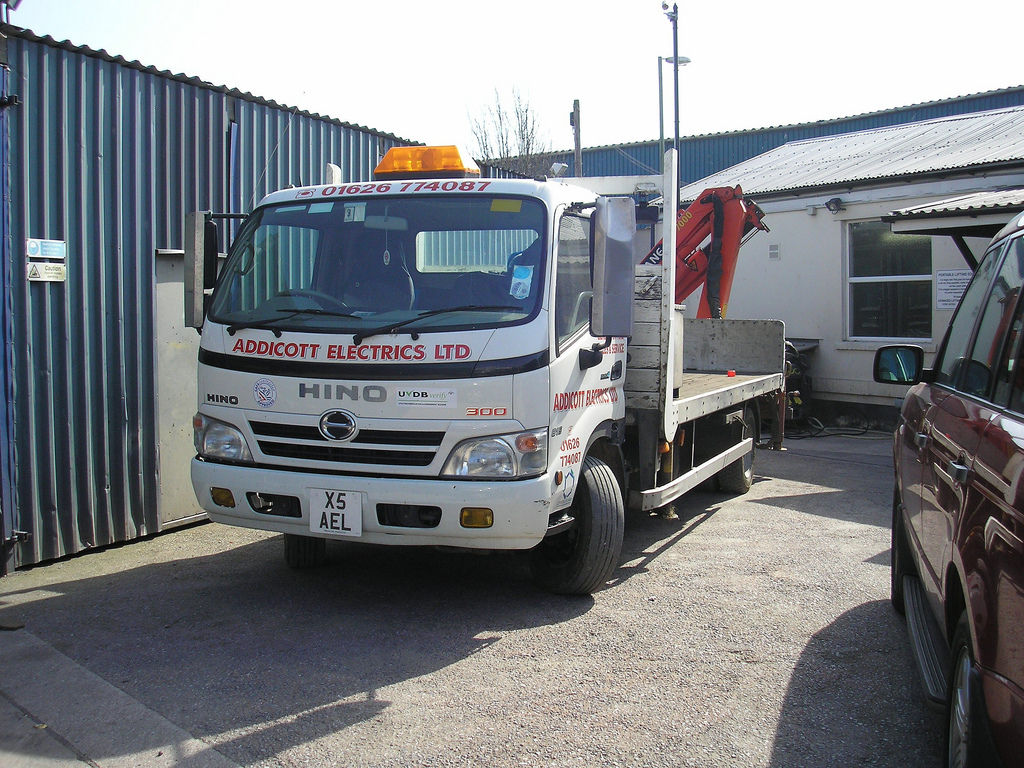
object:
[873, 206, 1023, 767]
truck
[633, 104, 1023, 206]
metal roof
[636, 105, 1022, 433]
building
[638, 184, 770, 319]
tractor arm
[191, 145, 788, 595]
truck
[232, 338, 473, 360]
text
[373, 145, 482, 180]
light